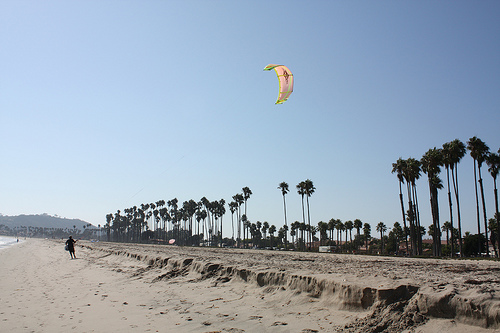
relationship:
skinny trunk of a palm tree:
[279, 190, 301, 251] [277, 179, 317, 194]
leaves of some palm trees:
[235, 185, 260, 203] [113, 193, 247, 213]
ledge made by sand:
[97, 242, 470, 330] [31, 233, 398, 331]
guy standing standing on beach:
[55, 231, 88, 267] [49, 216, 443, 330]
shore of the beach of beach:
[2, 223, 431, 328] [15, 226, 457, 326]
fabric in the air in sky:
[262, 63, 294, 105] [0, 1, 479, 244]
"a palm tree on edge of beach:
[271, 176, 304, 261] [0, 225, 60, 286]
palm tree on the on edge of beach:
[444, 132, 482, 259] [49, 216, 443, 330]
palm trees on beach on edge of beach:
[194, 181, 235, 249] [40, 223, 389, 330]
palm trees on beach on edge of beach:
[139, 192, 188, 247] [64, 227, 430, 321]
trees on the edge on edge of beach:
[96, 207, 172, 255] [47, 230, 413, 325]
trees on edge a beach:
[92, 136, 480, 248] [12, 230, 137, 314]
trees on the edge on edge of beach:
[187, 178, 331, 248] [47, 230, 413, 325]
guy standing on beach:
[65, 235, 79, 260] [43, 213, 260, 328]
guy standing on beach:
[65, 235, 79, 260] [44, 232, 355, 293]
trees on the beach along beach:
[120, 199, 190, 238] [74, 230, 453, 311]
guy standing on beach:
[65, 235, 79, 260] [76, 240, 417, 331]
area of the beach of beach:
[77, 252, 185, 332] [64, 243, 403, 330]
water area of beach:
[0, 230, 25, 252] [108, 240, 387, 331]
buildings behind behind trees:
[307, 224, 373, 262] [78, 151, 483, 263]